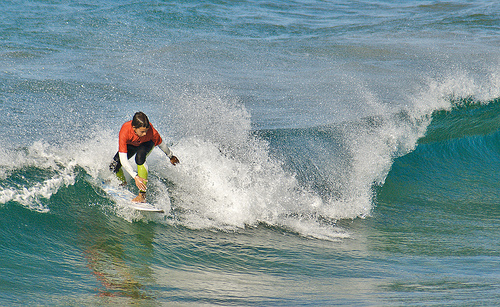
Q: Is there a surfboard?
A: Yes, there is a surfboard.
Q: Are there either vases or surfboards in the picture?
A: Yes, there is a surfboard.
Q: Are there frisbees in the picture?
A: No, there are no frisbees.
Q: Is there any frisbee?
A: No, there are no frisbees.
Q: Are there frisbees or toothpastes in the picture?
A: No, there are no frisbees or toothpastes.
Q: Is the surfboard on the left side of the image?
A: Yes, the surfboard is on the left of the image.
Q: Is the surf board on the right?
A: No, the surf board is on the left of the image.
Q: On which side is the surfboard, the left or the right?
A: The surfboard is on the left of the image.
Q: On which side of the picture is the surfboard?
A: The surfboard is on the left of the image.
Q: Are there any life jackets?
A: No, there are no life jackets.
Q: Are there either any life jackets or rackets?
A: No, there are no life jackets or rackets.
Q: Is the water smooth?
A: Yes, the water is smooth.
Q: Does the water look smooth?
A: Yes, the water is smooth.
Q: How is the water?
A: The water is smooth.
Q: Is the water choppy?
A: No, the water is smooth.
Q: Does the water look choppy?
A: No, the water is smooth.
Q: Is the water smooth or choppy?
A: The water is smooth.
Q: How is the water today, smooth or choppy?
A: The water is smooth.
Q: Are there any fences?
A: No, there are no fences.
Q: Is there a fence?
A: No, there are no fences.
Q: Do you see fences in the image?
A: No, there are no fences.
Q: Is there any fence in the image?
A: No, there are no fences.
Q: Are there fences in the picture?
A: No, there are no fences.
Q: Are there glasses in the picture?
A: No, there are no glasses.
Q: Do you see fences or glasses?
A: No, there are no glasses or fences.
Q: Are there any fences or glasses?
A: No, there are no glasses or fences.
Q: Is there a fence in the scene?
A: No, there are no fences.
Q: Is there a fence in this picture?
A: No, there are no fences.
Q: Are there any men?
A: No, there are no men.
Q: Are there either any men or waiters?
A: No, there are no men or waiters.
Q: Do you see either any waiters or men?
A: No, there are no men or waiters.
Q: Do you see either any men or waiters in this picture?
A: No, there are no men or waiters.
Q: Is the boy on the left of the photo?
A: Yes, the boy is on the left of the image.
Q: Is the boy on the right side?
A: No, the boy is on the left of the image.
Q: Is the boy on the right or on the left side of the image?
A: The boy is on the left of the image.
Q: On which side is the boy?
A: The boy is on the left of the image.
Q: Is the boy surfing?
A: Yes, the boy is surfing.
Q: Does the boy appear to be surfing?
A: Yes, the boy is surfing.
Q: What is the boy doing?
A: The boy is surfing.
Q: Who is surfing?
A: The boy is surfing.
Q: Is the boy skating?
A: No, the boy is surfing.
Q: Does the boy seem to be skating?
A: No, the boy is surfing.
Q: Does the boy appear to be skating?
A: No, the boy is surfing.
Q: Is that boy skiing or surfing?
A: The boy is surfing.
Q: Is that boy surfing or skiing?
A: The boy is surfing.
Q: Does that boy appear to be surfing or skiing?
A: The boy is surfing.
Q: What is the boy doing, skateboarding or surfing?
A: The boy is surfing.